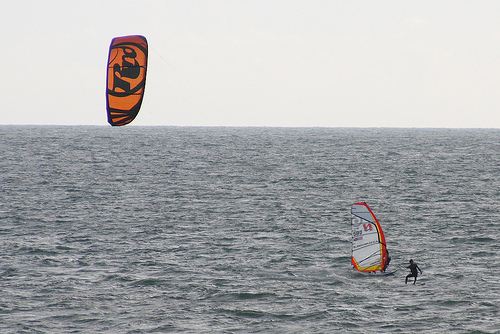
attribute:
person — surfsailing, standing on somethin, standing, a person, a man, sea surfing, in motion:
[403, 256, 424, 286]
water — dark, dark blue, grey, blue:
[1, 123, 499, 332]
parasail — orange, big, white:
[107, 34, 151, 128]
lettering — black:
[111, 46, 141, 94]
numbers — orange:
[361, 223, 374, 234]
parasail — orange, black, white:
[348, 198, 392, 278]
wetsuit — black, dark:
[402, 262, 423, 283]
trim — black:
[106, 34, 149, 129]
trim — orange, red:
[351, 198, 387, 276]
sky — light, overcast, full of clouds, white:
[1, 0, 497, 127]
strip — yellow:
[351, 259, 382, 274]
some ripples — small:
[2, 123, 498, 333]